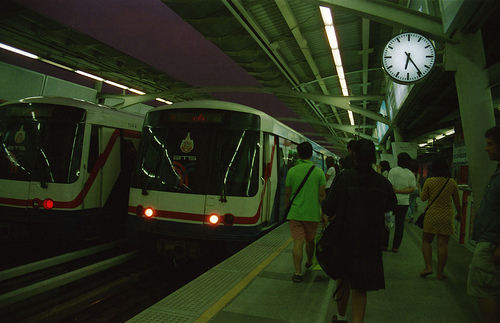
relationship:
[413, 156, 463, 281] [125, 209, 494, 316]
person walking on sidewalk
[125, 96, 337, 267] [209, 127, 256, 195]
window on train